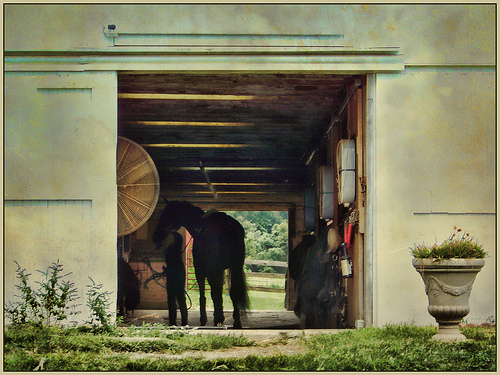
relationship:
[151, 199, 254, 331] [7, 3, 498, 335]
horse in stable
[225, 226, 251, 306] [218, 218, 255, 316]
hair on tail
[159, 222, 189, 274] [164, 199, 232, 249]
person by horse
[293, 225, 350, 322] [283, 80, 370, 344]
objects on wall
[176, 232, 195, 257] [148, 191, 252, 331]
strap hanging from horse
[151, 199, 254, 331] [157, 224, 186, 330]
horse taller than person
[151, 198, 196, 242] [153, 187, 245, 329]
head on horse